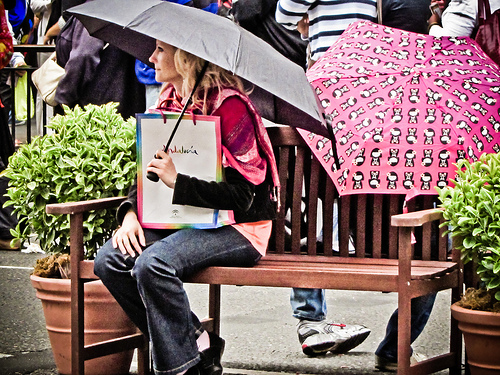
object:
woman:
[93, 39, 280, 375]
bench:
[46, 126, 476, 374]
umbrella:
[61, 0, 326, 182]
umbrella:
[293, 19, 499, 215]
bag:
[136, 98, 236, 229]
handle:
[144, 172, 159, 182]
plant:
[0, 102, 138, 279]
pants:
[93, 224, 261, 373]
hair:
[172, 47, 253, 116]